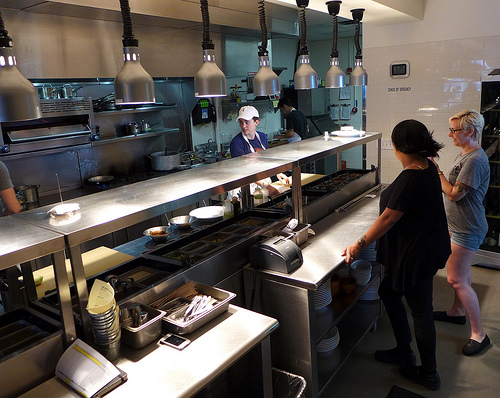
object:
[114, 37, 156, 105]
light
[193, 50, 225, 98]
light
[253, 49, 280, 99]
light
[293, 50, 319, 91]
light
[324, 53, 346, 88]
light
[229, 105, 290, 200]
woman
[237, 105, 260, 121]
cap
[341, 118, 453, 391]
woman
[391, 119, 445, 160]
hair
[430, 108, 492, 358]
woman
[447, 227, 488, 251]
shorts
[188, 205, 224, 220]
dish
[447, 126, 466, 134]
glasses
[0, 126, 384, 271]
shelf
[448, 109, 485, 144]
hair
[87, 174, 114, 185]
pan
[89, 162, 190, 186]
stove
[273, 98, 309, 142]
cook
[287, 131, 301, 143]
apron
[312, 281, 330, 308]
plates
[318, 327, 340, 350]
plates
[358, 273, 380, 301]
plates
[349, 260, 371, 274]
plates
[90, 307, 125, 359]
cups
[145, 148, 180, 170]
pot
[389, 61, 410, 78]
clock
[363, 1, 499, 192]
wall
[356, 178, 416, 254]
arm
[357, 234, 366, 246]
tattoo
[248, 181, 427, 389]
shelf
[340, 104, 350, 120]
clipboard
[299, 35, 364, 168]
wall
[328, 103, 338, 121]
clipboard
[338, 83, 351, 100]
clipboard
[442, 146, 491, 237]
shirt